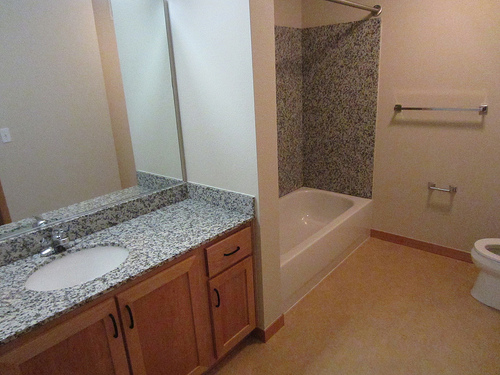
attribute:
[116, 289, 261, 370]
drawers — brown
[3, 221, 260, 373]
cabinets — wood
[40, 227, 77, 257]
tap — gray metal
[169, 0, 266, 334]
wall surface — white wall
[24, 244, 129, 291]
sink — white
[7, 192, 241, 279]
counter — black, white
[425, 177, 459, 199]
handle — small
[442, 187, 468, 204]
ground — toilet 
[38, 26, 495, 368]
bathroom — big clean  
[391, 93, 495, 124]
handle — pole 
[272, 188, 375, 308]
bathtub —  white 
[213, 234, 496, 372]
floor — brown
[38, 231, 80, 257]
tap — metallic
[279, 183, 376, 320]
basin —  shower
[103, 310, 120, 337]
handles — black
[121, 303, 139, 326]
handles — black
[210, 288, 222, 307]
handles — black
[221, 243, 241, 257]
handles — black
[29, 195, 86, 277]
faucet — silver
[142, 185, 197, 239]
surface — cemented ,  black , white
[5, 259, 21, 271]
handwash — white 